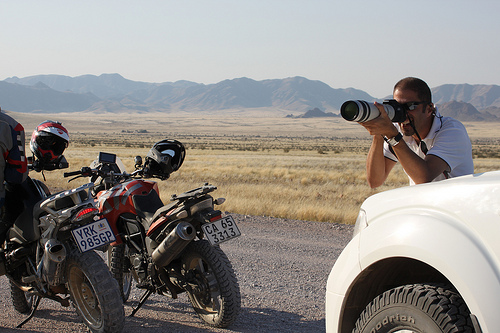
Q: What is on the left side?
A: Bikes.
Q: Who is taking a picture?
A: The man.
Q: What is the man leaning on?
A: White truck.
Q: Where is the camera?
A: Man's hands.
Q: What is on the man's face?
A: Glasses.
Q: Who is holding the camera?
A: The man.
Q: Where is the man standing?
A: The street.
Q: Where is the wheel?
A: On truck.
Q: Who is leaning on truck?
A: A man.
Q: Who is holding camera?
A: A man.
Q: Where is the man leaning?
A: On car.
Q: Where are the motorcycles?
A: Parked.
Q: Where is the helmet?
A: On motorcycle.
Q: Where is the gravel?
A: Road.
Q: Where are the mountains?
A: Background.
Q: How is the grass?
A: Dry.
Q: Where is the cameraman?
A: Near white vehicle.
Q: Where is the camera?
A: In front of face.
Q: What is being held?
A: A camera.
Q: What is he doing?
A: Taking pictures.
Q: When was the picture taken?
A: Daytime.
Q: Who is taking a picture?
A: The man.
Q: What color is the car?
A: White.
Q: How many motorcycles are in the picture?
A: Two.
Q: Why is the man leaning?
A: To take a picture.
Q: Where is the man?
A: Behind the car.